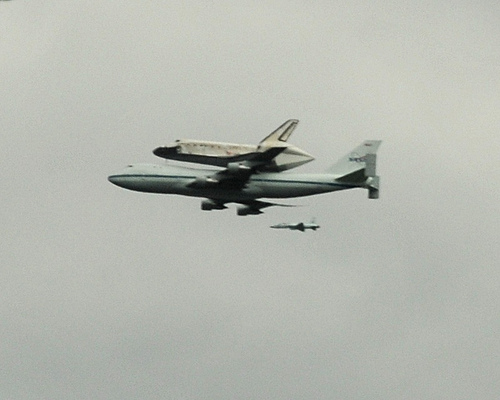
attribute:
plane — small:
[268, 214, 322, 234]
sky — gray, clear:
[1, 1, 484, 395]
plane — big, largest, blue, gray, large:
[105, 137, 383, 216]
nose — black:
[152, 144, 180, 159]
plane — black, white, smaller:
[151, 115, 315, 174]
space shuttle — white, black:
[151, 117, 318, 174]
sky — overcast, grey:
[109, 287, 191, 335]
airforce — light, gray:
[265, 223, 316, 241]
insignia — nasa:
[347, 148, 368, 167]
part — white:
[266, 116, 292, 144]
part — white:
[335, 146, 399, 204]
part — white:
[237, 135, 302, 171]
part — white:
[277, 142, 306, 171]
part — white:
[106, 165, 205, 201]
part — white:
[260, 170, 341, 202]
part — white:
[266, 222, 316, 235]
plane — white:
[155, 119, 313, 171]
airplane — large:
[107, 137, 384, 217]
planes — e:
[88, 103, 398, 251]